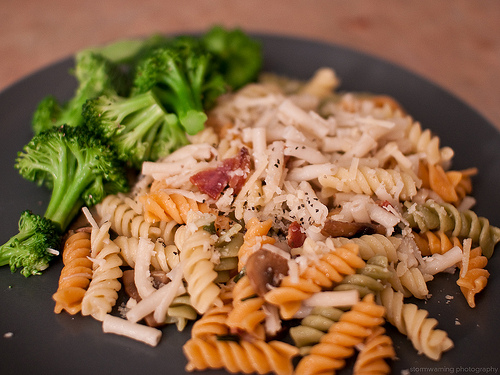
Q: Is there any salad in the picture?
A: Yes, there is salad.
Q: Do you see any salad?
A: Yes, there is salad.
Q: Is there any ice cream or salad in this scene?
A: Yes, there is salad.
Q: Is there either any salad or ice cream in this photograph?
A: Yes, there is salad.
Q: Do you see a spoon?
A: No, there are no spoons.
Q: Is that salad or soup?
A: That is salad.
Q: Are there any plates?
A: Yes, there is a plate.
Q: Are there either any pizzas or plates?
A: Yes, there is a plate.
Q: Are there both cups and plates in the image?
A: No, there is a plate but no cups.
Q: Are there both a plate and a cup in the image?
A: No, there is a plate but no cups.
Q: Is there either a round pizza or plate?
A: Yes, there is a round plate.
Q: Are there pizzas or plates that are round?
A: Yes, the plate is round.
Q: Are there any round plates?
A: Yes, there is a round plate.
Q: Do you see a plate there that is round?
A: Yes, there is a plate that is round.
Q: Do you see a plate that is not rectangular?
A: Yes, there is a round plate.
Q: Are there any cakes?
A: No, there are no cakes.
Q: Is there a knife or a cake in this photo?
A: No, there are no cakes or knives.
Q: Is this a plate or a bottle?
A: This is a plate.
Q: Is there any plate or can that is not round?
A: No, there is a plate but it is round.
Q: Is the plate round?
A: Yes, the plate is round.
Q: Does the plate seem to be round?
A: Yes, the plate is round.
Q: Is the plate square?
A: No, the plate is round.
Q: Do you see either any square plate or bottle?
A: No, there is a plate but it is round.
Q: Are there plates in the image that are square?
A: No, there is a plate but it is round.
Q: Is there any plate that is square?
A: No, there is a plate but it is round.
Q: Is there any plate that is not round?
A: No, there is a plate but it is round.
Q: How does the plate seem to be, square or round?
A: The plate is round.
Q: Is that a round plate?
A: Yes, that is a round plate.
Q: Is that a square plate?
A: No, that is a round plate.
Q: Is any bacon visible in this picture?
A: Yes, there is bacon.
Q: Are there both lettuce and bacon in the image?
A: No, there is bacon but no lettuce.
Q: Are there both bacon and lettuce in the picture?
A: No, there is bacon but no lettuce.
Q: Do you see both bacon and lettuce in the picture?
A: No, there is bacon but no lettuce.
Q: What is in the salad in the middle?
A: The bacon is in the salad.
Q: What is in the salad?
A: The bacon is in the salad.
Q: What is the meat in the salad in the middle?
A: The meat is bacon.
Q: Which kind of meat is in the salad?
A: The meat is bacon.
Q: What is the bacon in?
A: The bacon is in the salad.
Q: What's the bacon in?
A: The bacon is in the salad.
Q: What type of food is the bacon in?
A: The bacon is in the salad.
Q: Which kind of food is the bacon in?
A: The bacon is in the salad.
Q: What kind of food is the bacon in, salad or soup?
A: The bacon is in salad.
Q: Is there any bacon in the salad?
A: Yes, there is bacon in the salad.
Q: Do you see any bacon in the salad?
A: Yes, there is bacon in the salad.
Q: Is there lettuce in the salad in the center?
A: No, there is bacon in the salad.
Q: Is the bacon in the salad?
A: Yes, the bacon is in the salad.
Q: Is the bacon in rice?
A: No, the bacon is in the salad.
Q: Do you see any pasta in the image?
A: Yes, there is pasta.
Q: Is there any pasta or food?
A: Yes, there is pasta.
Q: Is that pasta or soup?
A: That is pasta.